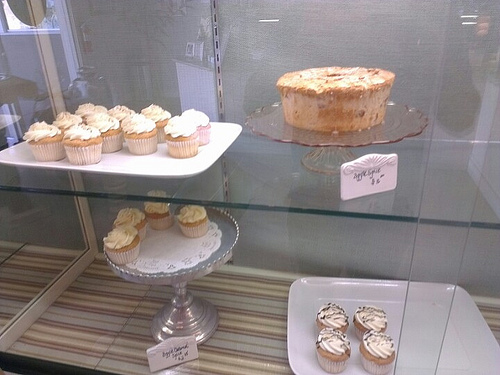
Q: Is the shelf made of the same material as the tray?
A: Yes, both the shelf and the tray are made of glass.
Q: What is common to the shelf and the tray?
A: The material, both the shelf and the tray are glass.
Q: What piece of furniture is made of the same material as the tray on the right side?
A: The shelf is made of the same material as the tray.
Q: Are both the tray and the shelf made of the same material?
A: Yes, both the tray and the shelf are made of glass.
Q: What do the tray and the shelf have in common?
A: The material, both the tray and the shelf are glass.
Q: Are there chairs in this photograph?
A: No, there are no chairs.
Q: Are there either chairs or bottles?
A: No, there are no chairs or bottles.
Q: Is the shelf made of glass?
A: Yes, the shelf is made of glass.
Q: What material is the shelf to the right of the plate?
A: The shelf is made of glass.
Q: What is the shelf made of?
A: The shelf is made of glass.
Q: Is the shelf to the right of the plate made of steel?
A: No, the shelf is made of glass.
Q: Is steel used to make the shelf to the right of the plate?
A: No, the shelf is made of glass.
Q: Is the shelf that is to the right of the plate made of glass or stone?
A: The shelf is made of glass.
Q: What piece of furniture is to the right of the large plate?
A: The piece of furniture is a shelf.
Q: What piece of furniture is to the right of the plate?
A: The piece of furniture is a shelf.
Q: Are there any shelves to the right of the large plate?
A: Yes, there is a shelf to the right of the plate.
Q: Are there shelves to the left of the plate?
A: No, the shelf is to the right of the plate.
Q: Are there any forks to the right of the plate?
A: No, there is a shelf to the right of the plate.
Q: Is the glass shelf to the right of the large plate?
A: Yes, the shelf is to the right of the plate.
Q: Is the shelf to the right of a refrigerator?
A: No, the shelf is to the right of the plate.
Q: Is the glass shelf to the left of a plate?
A: No, the shelf is to the right of a plate.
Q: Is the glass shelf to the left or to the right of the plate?
A: The shelf is to the right of the plate.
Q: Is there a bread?
A: No, there is no breads.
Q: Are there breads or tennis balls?
A: No, there are no breads or tennis balls.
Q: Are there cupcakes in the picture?
A: Yes, there is a cupcake.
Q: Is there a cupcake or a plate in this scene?
A: Yes, there is a cupcake.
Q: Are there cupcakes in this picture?
A: Yes, there is a cupcake.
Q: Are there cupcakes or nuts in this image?
A: Yes, there is a cupcake.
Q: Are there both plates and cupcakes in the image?
A: Yes, there are both a cupcake and a plate.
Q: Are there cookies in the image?
A: No, there are no cookies.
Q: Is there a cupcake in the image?
A: Yes, there is a cupcake.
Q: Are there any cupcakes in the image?
A: Yes, there is a cupcake.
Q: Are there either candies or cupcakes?
A: Yes, there is a cupcake.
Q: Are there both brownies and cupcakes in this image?
A: No, there is a cupcake but no brownies.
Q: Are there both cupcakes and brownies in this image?
A: No, there is a cupcake but no brownies.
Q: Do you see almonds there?
A: No, there are no almonds.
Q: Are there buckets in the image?
A: No, there are no buckets.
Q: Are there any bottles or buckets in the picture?
A: No, there are no buckets or bottles.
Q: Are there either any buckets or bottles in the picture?
A: No, there are no buckets or bottles.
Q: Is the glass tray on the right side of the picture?
A: Yes, the tray is on the right of the image.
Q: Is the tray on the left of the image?
A: No, the tray is on the right of the image.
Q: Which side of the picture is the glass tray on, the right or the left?
A: The tray is on the right of the image.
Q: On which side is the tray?
A: The tray is on the right of the image.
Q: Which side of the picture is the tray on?
A: The tray is on the right of the image.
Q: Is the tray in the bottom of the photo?
A: Yes, the tray is in the bottom of the image.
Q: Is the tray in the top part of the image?
A: No, the tray is in the bottom of the image.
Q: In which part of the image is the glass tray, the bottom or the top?
A: The tray is in the bottom of the image.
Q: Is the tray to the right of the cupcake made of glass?
A: Yes, the tray is made of glass.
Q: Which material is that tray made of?
A: The tray is made of glass.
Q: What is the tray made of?
A: The tray is made of glass.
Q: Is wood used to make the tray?
A: No, the tray is made of glass.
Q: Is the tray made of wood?
A: No, the tray is made of glass.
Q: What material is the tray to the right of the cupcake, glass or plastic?
A: The tray is made of glass.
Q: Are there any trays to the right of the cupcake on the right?
A: Yes, there is a tray to the right of the cupcake.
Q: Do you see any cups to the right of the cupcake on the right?
A: No, there is a tray to the right of the cupcake.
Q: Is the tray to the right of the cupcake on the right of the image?
A: Yes, the tray is to the right of the cupcake.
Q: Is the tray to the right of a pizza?
A: No, the tray is to the right of the cupcake.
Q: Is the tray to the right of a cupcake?
A: Yes, the tray is to the right of a cupcake.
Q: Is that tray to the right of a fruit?
A: No, the tray is to the right of a cupcake.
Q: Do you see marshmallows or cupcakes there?
A: Yes, there is a cupcake.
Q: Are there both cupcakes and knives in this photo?
A: No, there is a cupcake but no knives.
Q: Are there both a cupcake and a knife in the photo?
A: No, there is a cupcake but no knives.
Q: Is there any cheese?
A: No, there is no cheese.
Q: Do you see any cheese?
A: No, there is no cheese.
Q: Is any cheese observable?
A: No, there is no cheese.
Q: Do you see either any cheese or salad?
A: No, there are no cheese or salad.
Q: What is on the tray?
A: The cupcake is on the tray.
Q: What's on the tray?
A: The cupcake is on the tray.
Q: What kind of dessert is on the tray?
A: The dessert is a cupcake.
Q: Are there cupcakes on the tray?
A: Yes, there is a cupcake on the tray.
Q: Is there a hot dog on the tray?
A: No, there is a cupcake on the tray.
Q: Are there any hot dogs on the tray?
A: No, there is a cupcake on the tray.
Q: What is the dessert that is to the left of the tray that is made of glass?
A: The dessert is a cupcake.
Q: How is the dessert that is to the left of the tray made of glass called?
A: The dessert is a cupcake.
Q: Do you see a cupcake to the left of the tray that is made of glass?
A: Yes, there is a cupcake to the left of the tray.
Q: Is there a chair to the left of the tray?
A: No, there is a cupcake to the left of the tray.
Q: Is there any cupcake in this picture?
A: Yes, there is a cupcake.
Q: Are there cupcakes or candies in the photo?
A: Yes, there is a cupcake.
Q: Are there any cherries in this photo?
A: No, there are no cherries.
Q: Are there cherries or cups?
A: No, there are no cherries or cups.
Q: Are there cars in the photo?
A: No, there are no cars.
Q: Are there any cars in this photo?
A: No, there are no cars.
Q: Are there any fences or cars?
A: No, there are no cars or fences.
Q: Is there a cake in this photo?
A: Yes, there is a cake.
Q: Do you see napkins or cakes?
A: Yes, there is a cake.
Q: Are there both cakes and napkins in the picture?
A: No, there is a cake but no napkins.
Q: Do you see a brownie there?
A: No, there are no brownies.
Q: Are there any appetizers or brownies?
A: No, there are no brownies or appetizers.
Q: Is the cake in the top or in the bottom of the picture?
A: The cake is in the top of the image.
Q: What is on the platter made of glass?
A: The cake is on the platter.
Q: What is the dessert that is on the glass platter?
A: The dessert is a cake.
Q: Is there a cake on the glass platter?
A: Yes, there is a cake on the platter.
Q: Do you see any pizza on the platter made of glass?
A: No, there is a cake on the platter.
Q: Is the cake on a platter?
A: Yes, the cake is on a platter.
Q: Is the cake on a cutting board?
A: No, the cake is on a platter.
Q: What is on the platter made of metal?
A: The cake is on the platter.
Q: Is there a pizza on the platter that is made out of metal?
A: No, there is a cake on the platter.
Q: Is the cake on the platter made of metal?
A: Yes, the cake is on the platter.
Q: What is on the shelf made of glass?
A: The cake is on the shelf.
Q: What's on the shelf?
A: The cake is on the shelf.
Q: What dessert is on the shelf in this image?
A: The dessert is a cake.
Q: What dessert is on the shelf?
A: The dessert is a cake.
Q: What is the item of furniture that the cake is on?
A: The piece of furniture is a shelf.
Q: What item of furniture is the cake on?
A: The cake is on the shelf.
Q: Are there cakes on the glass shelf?
A: Yes, there is a cake on the shelf.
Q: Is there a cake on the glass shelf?
A: Yes, there is a cake on the shelf.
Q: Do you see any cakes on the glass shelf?
A: Yes, there is a cake on the shelf.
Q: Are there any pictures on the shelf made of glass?
A: No, there is a cake on the shelf.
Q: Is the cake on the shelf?
A: Yes, the cake is on the shelf.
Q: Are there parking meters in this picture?
A: No, there are no parking meters.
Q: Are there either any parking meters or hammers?
A: No, there are no parking meters or hammers.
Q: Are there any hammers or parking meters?
A: No, there are no parking meters or hammers.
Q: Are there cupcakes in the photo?
A: Yes, there is a cupcake.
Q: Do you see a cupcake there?
A: Yes, there is a cupcake.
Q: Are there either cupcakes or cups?
A: Yes, there is a cupcake.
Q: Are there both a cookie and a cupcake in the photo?
A: No, there is a cupcake but no cookies.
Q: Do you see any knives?
A: No, there are no knives.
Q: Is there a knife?
A: No, there are no knives.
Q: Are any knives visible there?
A: No, there are no knives.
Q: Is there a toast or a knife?
A: No, there are no knives or toasts.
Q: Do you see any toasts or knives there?
A: No, there are no knives or toasts.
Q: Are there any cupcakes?
A: Yes, there is a cupcake.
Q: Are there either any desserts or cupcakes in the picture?
A: Yes, there is a cupcake.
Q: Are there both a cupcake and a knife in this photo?
A: No, there is a cupcake but no knives.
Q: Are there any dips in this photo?
A: No, there are no dips.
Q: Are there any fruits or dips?
A: No, there are no dips or fruits.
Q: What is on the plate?
A: The cupcake is on the plate.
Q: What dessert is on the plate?
A: The dessert is a cupcake.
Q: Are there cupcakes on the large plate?
A: Yes, there is a cupcake on the plate.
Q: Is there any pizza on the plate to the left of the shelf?
A: No, there is a cupcake on the plate.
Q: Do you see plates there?
A: Yes, there is a plate.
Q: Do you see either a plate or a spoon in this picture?
A: Yes, there is a plate.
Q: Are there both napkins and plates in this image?
A: No, there is a plate but no napkins.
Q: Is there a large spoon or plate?
A: Yes, there is a large plate.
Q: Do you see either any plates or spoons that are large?
A: Yes, the plate is large.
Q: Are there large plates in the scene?
A: Yes, there is a large plate.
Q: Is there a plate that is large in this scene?
A: Yes, there is a large plate.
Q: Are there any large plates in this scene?
A: Yes, there is a large plate.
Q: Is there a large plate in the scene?
A: Yes, there is a large plate.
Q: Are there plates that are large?
A: Yes, there is a plate that is large.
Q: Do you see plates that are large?
A: Yes, there is a plate that is large.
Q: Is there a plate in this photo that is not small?
A: Yes, there is a large plate.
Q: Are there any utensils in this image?
A: No, there are no utensils.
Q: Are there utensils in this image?
A: No, there are no utensils.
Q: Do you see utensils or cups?
A: No, there are no utensils or cups.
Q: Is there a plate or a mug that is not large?
A: No, there is a plate but it is large.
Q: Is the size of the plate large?
A: Yes, the plate is large.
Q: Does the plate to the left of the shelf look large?
A: Yes, the plate is large.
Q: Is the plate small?
A: No, the plate is large.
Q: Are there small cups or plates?
A: No, there is a plate but it is large.